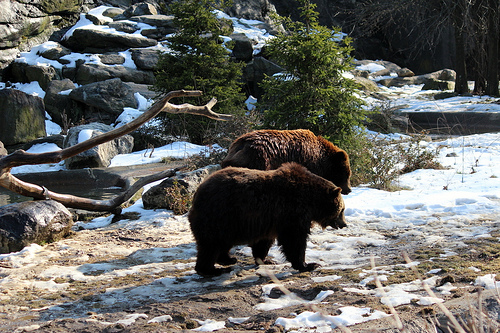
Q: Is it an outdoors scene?
A: Yes, it is outdoors.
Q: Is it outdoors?
A: Yes, it is outdoors.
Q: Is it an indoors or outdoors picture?
A: It is outdoors.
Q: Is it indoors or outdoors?
A: It is outdoors.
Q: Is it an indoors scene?
A: No, it is outdoors.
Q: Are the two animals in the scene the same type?
A: Yes, all the animals are bears.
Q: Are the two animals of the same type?
A: Yes, all the animals are bears.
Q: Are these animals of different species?
A: No, all the animals are bears.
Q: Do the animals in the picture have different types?
A: No, all the animals are bears.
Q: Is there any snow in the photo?
A: Yes, there is snow.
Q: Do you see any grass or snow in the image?
A: Yes, there is snow.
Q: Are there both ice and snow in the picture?
A: No, there is snow but no ice.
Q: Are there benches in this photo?
A: No, there are no benches.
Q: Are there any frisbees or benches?
A: No, there are no benches or frisbees.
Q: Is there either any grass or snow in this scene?
A: Yes, there is snow.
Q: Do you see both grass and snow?
A: Yes, there are both snow and grass.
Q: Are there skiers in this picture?
A: No, there are no skiers.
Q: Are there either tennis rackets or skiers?
A: No, there are no skiers or tennis rackets.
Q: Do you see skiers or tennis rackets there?
A: No, there are no skiers or tennis rackets.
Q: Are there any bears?
A: Yes, there is a bear.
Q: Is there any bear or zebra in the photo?
A: Yes, there is a bear.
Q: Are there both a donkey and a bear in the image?
A: No, there is a bear but no donkeys.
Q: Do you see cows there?
A: No, there are no cows.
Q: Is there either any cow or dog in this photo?
A: No, there are no cows or dogs.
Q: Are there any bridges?
A: No, there are no bridges.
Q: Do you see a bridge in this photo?
A: No, there are no bridges.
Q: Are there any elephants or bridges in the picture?
A: No, there are no bridges or elephants.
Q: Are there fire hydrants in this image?
A: No, there are no fire hydrants.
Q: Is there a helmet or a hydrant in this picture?
A: No, there are no fire hydrants or helmets.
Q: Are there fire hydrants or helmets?
A: No, there are no fire hydrants or helmets.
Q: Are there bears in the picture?
A: Yes, there is a bear.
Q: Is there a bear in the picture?
A: Yes, there is a bear.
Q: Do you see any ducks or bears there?
A: Yes, there is a bear.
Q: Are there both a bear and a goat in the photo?
A: No, there is a bear but no goats.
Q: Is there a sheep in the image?
A: No, there is no sheep.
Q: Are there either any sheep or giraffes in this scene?
A: No, there are no sheep or giraffes.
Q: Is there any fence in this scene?
A: No, there are no fences.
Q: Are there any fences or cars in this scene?
A: No, there are no fences or cars.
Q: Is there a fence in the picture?
A: No, there are no fences.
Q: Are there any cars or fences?
A: No, there are no fences or cars.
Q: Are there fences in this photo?
A: No, there are no fences.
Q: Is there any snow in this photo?
A: Yes, there is snow.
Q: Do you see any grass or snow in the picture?
A: Yes, there is snow.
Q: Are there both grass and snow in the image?
A: Yes, there are both snow and grass.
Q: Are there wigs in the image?
A: No, there are no wigs.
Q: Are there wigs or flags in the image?
A: No, there are no wigs or flags.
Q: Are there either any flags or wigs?
A: No, there are no wigs or flags.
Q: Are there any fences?
A: No, there are no fences.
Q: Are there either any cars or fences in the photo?
A: No, there are no fences or cars.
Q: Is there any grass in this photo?
A: Yes, there is grass.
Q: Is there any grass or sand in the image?
A: Yes, there is grass.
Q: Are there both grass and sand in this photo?
A: No, there is grass but no sand.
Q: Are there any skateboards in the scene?
A: No, there are no skateboards.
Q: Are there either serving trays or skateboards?
A: No, there are no skateboards or serving trays.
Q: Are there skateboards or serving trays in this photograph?
A: No, there are no skateboards or serving trays.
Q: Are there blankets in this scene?
A: No, there are no blankets.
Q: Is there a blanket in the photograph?
A: No, there are no blankets.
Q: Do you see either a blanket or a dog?
A: No, there are no blankets or dogs.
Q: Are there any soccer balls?
A: No, there are no soccer balls.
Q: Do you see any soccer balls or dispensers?
A: No, there are no soccer balls or dispensers.